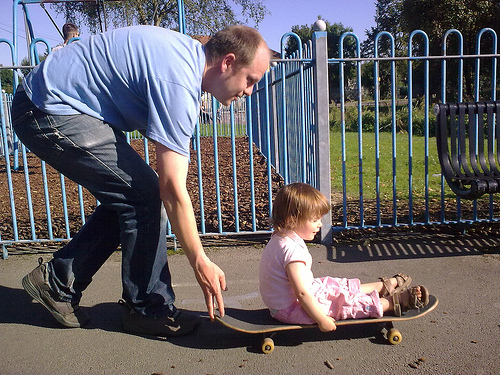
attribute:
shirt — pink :
[255, 229, 307, 311]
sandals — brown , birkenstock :
[375, 268, 427, 312]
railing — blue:
[0, 12, 498, 260]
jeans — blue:
[3, 92, 168, 312]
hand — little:
[315, 310, 345, 340]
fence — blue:
[4, 29, 498, 254]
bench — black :
[432, 102, 499, 236]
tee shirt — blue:
[7, 6, 288, 216]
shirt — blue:
[15, 38, 207, 154]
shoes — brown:
[378, 275, 433, 315]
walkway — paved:
[5, 228, 499, 374]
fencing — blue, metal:
[5, 32, 496, 218]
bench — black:
[438, 98, 499, 211]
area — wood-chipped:
[333, 128, 437, 199]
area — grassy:
[195, 136, 260, 219]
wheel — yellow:
[258, 337, 276, 354]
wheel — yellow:
[388, 326, 403, 346]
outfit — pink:
[257, 231, 385, 324]